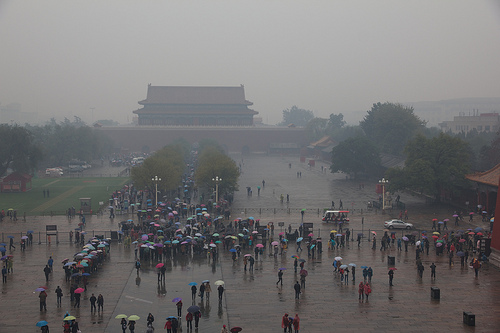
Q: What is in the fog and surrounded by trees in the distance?
A: Asian-style building.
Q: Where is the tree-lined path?
A: Leading to large building.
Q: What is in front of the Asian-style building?
A: Large wall.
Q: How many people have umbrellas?
A: Large group.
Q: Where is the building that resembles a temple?
A: Distance behind wall.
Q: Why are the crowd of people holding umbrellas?
A: Inclement weather.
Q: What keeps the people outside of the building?
A: Fence and wall.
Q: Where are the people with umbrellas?
A: Front courtyard.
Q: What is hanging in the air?
A: Fog.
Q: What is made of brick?
A: Ground.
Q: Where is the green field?
A: Along the walkway.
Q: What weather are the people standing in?
A: Rain.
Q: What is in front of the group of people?
A: A building.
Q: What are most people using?
A: An umbrella.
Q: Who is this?
A: A crowd of people.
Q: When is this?
A: During the day.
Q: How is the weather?
A: Rain.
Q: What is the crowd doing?
A: Walking.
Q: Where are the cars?
A: In the parking lot.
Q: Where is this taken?
A: On the street.